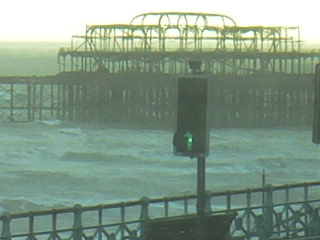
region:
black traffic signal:
[171, 57, 215, 238]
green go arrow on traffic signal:
[182, 128, 199, 152]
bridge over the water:
[1, 11, 318, 129]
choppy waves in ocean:
[32, 126, 157, 193]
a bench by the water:
[124, 212, 248, 238]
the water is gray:
[28, 125, 133, 185]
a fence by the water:
[242, 181, 316, 239]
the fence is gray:
[20, 202, 120, 239]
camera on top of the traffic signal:
[187, 56, 203, 75]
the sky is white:
[28, 4, 69, 41]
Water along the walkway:
[50, 135, 103, 167]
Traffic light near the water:
[167, 71, 226, 176]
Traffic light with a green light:
[162, 58, 229, 164]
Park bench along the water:
[131, 206, 218, 238]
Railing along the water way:
[95, 197, 239, 231]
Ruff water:
[40, 142, 104, 182]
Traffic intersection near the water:
[158, 48, 304, 224]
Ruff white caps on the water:
[44, 116, 108, 162]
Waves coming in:
[27, 65, 261, 217]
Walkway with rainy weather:
[62, 62, 174, 235]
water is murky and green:
[14, 122, 176, 180]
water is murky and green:
[19, 112, 167, 190]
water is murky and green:
[13, 144, 206, 196]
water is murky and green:
[24, 144, 121, 192]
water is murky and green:
[6, 129, 173, 183]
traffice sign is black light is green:
[166, 71, 211, 160]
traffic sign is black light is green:
[156, 91, 218, 158]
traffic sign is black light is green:
[175, 84, 208, 153]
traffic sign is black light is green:
[185, 91, 206, 169]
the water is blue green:
[39, 123, 122, 192]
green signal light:
[162, 63, 200, 161]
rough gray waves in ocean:
[36, 132, 65, 161]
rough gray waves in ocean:
[79, 160, 108, 184]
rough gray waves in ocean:
[125, 148, 149, 165]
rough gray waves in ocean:
[8, 171, 42, 189]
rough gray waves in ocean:
[124, 177, 161, 205]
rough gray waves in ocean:
[227, 139, 256, 164]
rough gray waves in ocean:
[216, 153, 237, 168]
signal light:
[174, 72, 205, 160]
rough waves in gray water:
[15, 134, 45, 155]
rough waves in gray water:
[98, 169, 120, 185]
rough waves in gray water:
[230, 142, 248, 159]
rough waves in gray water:
[260, 130, 285, 151]